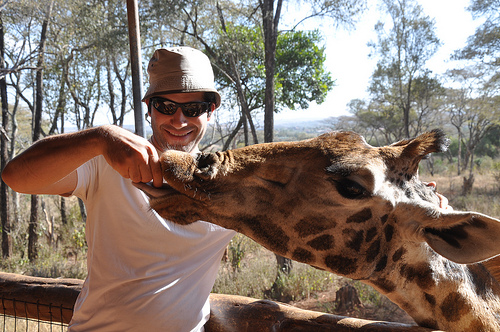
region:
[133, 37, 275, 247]
man with fingers in giraffe mouth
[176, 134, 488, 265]
large giraffe head with tongue out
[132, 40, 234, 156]
man in a hat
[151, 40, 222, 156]
man in a tan hat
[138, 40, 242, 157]
man in sunglasses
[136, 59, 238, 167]
man in black sunglasses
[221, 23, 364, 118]
large leafy green tree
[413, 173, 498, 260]
ear of a giraffe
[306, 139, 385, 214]
eye of a giraffe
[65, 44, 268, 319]
man in a white t-shirt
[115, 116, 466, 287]
large head of giraffe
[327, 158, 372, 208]
black eye of giraffe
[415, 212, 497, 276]
white and brown ear of giraffe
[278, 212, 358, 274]
white and brown spots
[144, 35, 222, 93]
small tan hat on head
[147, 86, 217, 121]
black sunglasses on face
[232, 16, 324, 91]
green leaves on tree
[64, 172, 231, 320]
white t shirt on man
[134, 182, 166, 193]
small tongue of giraffe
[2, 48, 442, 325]
man feeding food to giraffe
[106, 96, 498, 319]
this is a giraffe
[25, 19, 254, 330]
this is a man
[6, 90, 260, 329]
man wearing a white shirt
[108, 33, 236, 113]
man is wearing a hat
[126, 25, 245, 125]
mans hat is khaki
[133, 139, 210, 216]
giraffe has tongue out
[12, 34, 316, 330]
man is feeding the giraffe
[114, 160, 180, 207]
this is a giraffe tongue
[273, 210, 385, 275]
brown spots on giraffe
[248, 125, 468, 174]
brown hair on giraffe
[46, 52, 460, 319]
man feeding a giraffe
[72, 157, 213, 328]
man wearing a white shirt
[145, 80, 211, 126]
man wearing black sunglasses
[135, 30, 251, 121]
man wearing a hat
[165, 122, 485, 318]
brown spotted giraffe by fence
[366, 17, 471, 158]
tall tree in back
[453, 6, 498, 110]
tall tree in back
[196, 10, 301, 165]
tall tree in back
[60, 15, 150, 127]
tall tree in back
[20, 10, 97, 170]
tall tree in back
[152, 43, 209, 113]
This man has a large hat here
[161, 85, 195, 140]
This man has a pair of sunglasses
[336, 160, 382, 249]
This giraffe has a large eye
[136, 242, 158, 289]
This man has a white t-shirt here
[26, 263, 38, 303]
There is a large piece of wood fencing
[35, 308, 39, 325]
There is silver fence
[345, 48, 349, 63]
There is a light white sky here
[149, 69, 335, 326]
This photo is very lovely